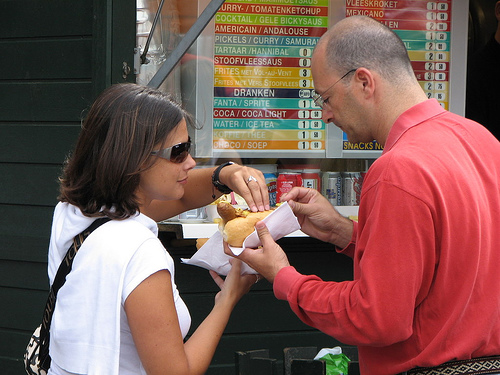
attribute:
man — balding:
[293, 13, 498, 373]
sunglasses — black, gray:
[145, 137, 201, 165]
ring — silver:
[244, 174, 259, 186]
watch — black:
[211, 156, 238, 193]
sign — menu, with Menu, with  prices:
[197, 7, 456, 155]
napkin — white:
[231, 209, 300, 253]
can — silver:
[318, 168, 344, 207]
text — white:
[215, 33, 319, 47]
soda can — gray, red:
[344, 169, 368, 211]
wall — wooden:
[9, 11, 81, 163]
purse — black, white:
[17, 296, 61, 370]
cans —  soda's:
[261, 166, 368, 205]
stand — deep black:
[16, 8, 482, 365]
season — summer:
[11, 10, 500, 367]